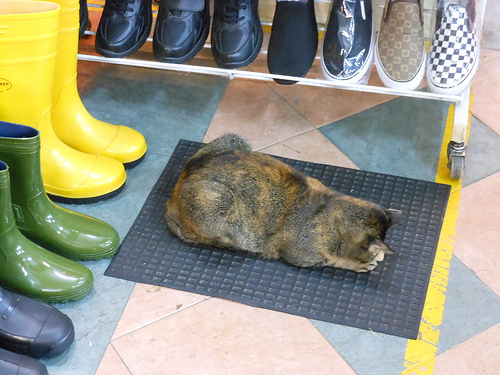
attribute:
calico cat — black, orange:
[168, 131, 409, 283]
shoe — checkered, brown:
[373, 0, 426, 92]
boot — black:
[4, 3, 134, 203]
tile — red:
[347, 108, 382, 131]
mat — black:
[384, 207, 466, 333]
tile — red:
[225, 81, 337, 165]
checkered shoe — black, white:
[432, 15, 477, 90]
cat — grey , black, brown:
[162, 132, 404, 274]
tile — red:
[467, 45, 499, 135]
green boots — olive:
[2, 127, 114, 296]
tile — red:
[154, 311, 281, 356]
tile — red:
[123, 284, 214, 325]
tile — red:
[255, 67, 432, 132]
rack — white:
[61, 0, 483, 188]